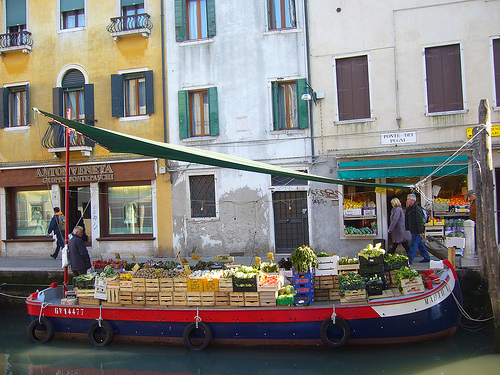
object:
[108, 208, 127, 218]
window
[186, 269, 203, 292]
carton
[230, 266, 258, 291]
carton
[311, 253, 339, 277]
carton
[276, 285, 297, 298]
produce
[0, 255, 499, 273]
road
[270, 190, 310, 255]
door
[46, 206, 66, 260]
man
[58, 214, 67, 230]
backpack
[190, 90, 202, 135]
window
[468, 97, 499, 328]
pole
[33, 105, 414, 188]
tarp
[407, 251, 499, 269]
dock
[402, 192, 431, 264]
man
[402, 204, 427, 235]
jacket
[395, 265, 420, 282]
produce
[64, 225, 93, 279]
man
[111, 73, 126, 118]
shutter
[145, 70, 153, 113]
shutter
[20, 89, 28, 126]
shutter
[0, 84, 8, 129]
shutter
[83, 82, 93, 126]
shutter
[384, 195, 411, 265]
woman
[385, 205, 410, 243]
grey coat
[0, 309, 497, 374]
river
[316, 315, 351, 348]
tire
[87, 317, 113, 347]
tire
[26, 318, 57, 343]
tire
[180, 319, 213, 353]
tire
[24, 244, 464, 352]
boat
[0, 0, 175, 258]
building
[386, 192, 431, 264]
couple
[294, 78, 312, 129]
window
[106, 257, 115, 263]
food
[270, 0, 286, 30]
shutter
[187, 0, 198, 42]
shutter